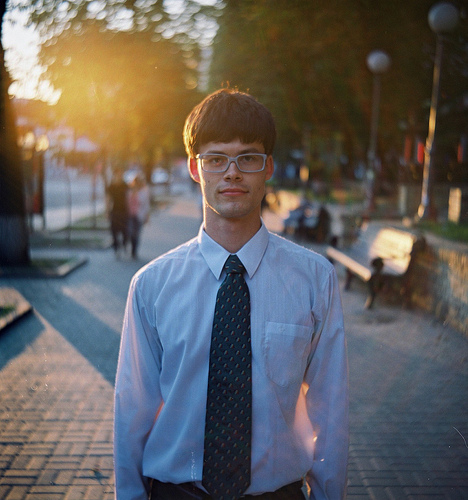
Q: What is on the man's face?
A: Glasses.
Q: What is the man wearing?
A: A shirt and tie.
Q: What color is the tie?
A: Blue.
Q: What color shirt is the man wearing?
A: White.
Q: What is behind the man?
A: A park.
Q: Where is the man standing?
A: On the sidewalk.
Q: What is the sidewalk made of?
A: Bricks.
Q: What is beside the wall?
A: A park bench.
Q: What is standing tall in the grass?
A: Lamp posts.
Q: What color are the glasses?
A: White.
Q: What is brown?
A: Guys hair.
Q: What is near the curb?
A: Tree.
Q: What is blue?
A: Tie.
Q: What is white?
A: Shirt.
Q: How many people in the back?
A: 2.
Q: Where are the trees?
A: Background.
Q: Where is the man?
A: On the sidewalk.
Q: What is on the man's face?
A: Glasses.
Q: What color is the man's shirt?
A: White.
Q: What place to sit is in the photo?
A: A bench.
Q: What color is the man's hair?
A: Brown.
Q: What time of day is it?
A: Evening.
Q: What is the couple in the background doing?
A: Walking.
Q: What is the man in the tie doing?
A: Looking at the camera.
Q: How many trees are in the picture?
A: 5.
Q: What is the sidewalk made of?
A: Bricks.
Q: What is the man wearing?
A: A tie.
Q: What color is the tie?
A: Blue.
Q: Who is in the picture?
A: A man.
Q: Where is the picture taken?
A: On the sidewalk.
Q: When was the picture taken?
A: At sunset.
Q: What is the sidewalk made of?
A: Stones.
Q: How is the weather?
A: It is clear.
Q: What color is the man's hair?
A: Brown.